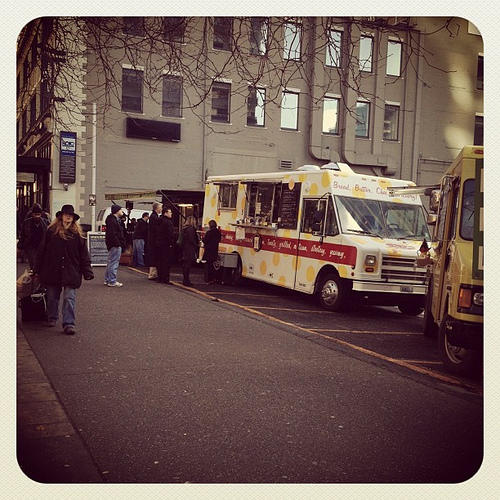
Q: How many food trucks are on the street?
A: 2.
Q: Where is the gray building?
A: Be hide the food trucks.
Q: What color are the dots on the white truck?
A: Yellow.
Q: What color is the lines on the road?
A: Yellow.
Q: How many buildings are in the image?
A: 1.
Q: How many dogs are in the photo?
A: 0.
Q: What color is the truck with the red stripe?
A: White.